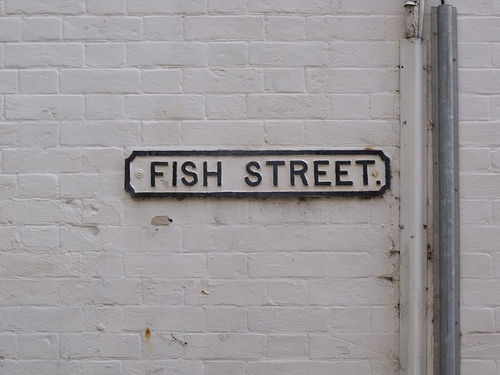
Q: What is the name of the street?
A: Fish street.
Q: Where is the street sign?
A: Side of building.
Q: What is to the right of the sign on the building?
A: Metal and white poles.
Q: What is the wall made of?
A: White bricks.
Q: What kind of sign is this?
A: Black sign.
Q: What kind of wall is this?
A: White brick wall.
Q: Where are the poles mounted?
A: Brick wall.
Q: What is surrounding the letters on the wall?
A: Black rectangle.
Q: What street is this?
A: FISH STREET.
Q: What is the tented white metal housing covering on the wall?
A: Cables.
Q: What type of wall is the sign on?
A: A brick wall.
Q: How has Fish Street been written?
A: In all capitals.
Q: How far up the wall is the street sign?
A: Halfway.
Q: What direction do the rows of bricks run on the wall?
A: Horizontally.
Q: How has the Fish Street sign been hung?
A: Mounted on bricks.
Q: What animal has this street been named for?
A: Fish.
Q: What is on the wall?
A: Sign.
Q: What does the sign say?
A: Fish street.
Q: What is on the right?
A: Wire protector.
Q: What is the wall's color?
A: White.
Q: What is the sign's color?
A: White and blue.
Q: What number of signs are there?
A: 1.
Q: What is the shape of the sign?
A: Rectangular.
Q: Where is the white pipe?
A: Next to the sign.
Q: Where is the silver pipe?
A: Next to the white pipe.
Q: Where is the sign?
A: On the wall.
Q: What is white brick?
A: The wall.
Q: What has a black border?
A: The sign.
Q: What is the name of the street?
A: Fish Street.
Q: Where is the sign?
A: On a building.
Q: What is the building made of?
A: Brick.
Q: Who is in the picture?
A: No one.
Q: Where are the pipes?
A: To the right of the sign.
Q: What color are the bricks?
A: White.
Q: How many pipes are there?
A: Two.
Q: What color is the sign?
A: White and black.